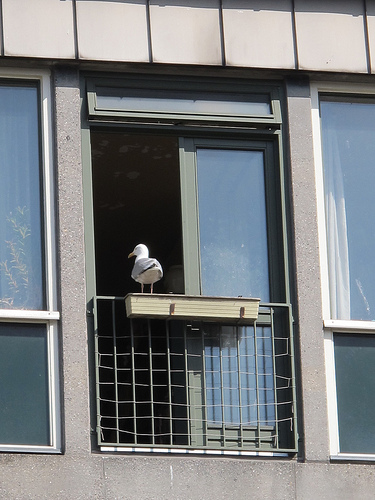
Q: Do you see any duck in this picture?
A: No, there are no ducks.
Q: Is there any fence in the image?
A: Yes, there is a fence.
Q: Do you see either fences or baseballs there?
A: Yes, there is a fence.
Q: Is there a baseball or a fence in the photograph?
A: Yes, there is a fence.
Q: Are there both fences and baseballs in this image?
A: No, there is a fence but no baseballs.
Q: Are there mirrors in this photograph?
A: No, there are no mirrors.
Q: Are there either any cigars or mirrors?
A: No, there are no mirrors or cigars.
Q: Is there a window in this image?
A: Yes, there is a window.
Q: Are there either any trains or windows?
A: Yes, there is a window.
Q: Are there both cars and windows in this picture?
A: No, there is a window but no cars.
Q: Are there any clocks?
A: No, there are no clocks.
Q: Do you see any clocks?
A: No, there are no clocks.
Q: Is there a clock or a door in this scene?
A: No, there are no clocks or doors.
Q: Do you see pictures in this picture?
A: No, there are no pictures.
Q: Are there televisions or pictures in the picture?
A: No, there are no pictures or televisions.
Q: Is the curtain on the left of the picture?
A: No, the curtain is on the right of the image.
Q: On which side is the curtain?
A: The curtain is on the right of the image.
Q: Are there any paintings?
A: No, there are no paintings.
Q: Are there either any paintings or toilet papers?
A: No, there are no paintings or toilet papers.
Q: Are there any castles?
A: No, there are no castles.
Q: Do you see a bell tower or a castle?
A: No, there are no castles or bell towers.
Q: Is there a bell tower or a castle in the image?
A: No, there are no castles or bell towers.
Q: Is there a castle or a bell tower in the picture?
A: No, there are no castles or bell towers.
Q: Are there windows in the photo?
A: Yes, there is a window.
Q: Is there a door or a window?
A: Yes, there is a window.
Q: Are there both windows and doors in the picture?
A: No, there is a window but no doors.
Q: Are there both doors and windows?
A: No, there is a window but no doors.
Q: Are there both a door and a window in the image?
A: No, there is a window but no doors.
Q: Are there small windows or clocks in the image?
A: Yes, there is a small window.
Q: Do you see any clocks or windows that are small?
A: Yes, the window is small.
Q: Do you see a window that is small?
A: Yes, there is a small window.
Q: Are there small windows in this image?
A: Yes, there is a small window.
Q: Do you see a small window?
A: Yes, there is a small window.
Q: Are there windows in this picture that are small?
A: Yes, there is a window that is small.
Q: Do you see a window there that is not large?
A: Yes, there is a small window.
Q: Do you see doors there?
A: No, there are no doors.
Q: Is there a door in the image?
A: No, there are no doors.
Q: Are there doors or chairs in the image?
A: No, there are no doors or chairs.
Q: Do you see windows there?
A: Yes, there is a window.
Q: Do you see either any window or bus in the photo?
A: Yes, there is a window.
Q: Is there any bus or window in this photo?
A: Yes, there is a window.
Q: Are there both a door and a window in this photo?
A: No, there is a window but no doors.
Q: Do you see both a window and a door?
A: No, there is a window but no doors.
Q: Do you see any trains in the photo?
A: No, there are no trains.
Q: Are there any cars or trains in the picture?
A: No, there are no trains or cars.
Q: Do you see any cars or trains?
A: No, there are no trains or cars.